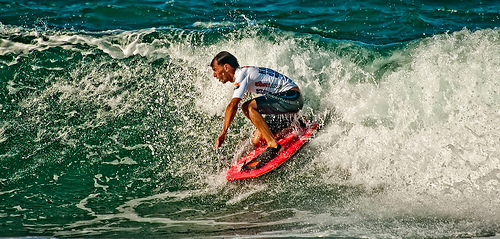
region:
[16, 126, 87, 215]
Water is blue color.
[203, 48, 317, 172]
One man is surfing.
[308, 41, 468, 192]
Waves are white color.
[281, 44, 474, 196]
water is splashing.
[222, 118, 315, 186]
Surfing board is red color.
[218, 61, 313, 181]
Man is standing on the surfing board.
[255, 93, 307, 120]
Man is wearing blue shorts.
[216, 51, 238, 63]
Hair is black color.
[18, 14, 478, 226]
Day time picture.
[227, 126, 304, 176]
One surfing board is seen.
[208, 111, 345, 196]
red surfboard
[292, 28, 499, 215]
large white wave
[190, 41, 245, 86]
short brown hair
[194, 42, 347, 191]
surfer is riding the big wave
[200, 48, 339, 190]
surfer is crouched down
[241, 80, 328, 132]
man is wearing shorts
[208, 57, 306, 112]
surfer is wearing a white top with writing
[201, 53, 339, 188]
surfer is wet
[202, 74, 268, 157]
arms are in front of him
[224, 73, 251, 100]
emblem on the shoulder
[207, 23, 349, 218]
Man surfing in the ocean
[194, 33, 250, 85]
Man with dark hair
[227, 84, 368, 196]
Red surfboard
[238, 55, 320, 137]
Man with swim trunks and tshirt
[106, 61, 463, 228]
Surfing on an ocean wave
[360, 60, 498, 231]
Ocean wave with white cap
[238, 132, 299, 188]
Wearing flippers while riding surfboard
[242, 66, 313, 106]
Tshirt has writing on it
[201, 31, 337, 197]
The man looks surprised by the wave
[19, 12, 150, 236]
The ocean water is a greenish blue color.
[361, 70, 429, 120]
part of a water splash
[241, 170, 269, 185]
part of a swimming board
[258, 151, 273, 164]
surface of a board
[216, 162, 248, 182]
edge of a board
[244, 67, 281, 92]
part of a white top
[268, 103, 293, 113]
part of a short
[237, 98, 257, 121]
part of a knee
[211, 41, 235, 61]
hair of a man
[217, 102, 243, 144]
part of an arm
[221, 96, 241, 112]
part of an elbow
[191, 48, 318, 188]
man surfing in ocean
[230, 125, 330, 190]
man riding red surf board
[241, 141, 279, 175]
man wearing black fin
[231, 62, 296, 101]
man wearing white shirt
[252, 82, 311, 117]
man wearing black shorts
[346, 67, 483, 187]
white foam of ocean wave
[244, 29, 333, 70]
white foam of ocean wave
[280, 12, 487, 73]
green and white ocean wave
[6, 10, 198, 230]
green and white ocean wave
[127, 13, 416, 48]
green and white ocean wave